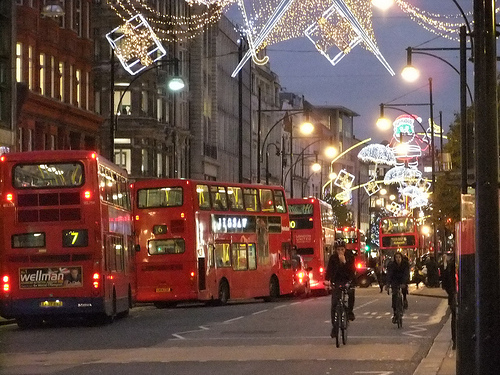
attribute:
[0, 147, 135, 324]
bus — double-decker, red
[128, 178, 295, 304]
bus — double-decker, reflective, red, bright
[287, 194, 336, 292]
bus — double-decker, red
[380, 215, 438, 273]
bus — double-decker, red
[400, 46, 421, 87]
light — on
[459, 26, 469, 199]
pole — black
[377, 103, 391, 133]
light — on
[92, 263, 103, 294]
taillight — red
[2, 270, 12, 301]
taillight — red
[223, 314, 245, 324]
line — painted, white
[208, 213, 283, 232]
sign — black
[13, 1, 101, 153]
building — lit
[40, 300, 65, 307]
plate — yellow